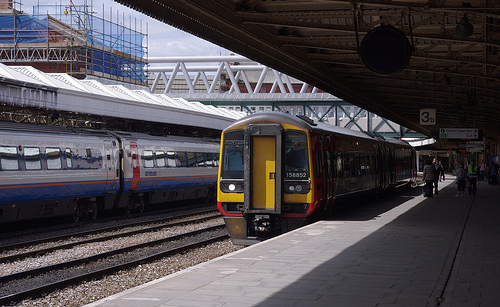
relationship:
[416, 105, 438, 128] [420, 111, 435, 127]
sign says 3b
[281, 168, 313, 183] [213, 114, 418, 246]
number on train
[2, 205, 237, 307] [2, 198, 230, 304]
gravel around tracks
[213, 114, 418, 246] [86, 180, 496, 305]
train near platform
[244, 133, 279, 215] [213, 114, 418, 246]
door on train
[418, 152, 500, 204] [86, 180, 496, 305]
people on platform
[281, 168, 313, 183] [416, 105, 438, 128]
number on sign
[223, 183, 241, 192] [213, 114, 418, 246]
headlights on train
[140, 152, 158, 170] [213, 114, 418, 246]
window on train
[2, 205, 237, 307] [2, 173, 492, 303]
rocks on ground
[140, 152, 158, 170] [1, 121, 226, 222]
window on train